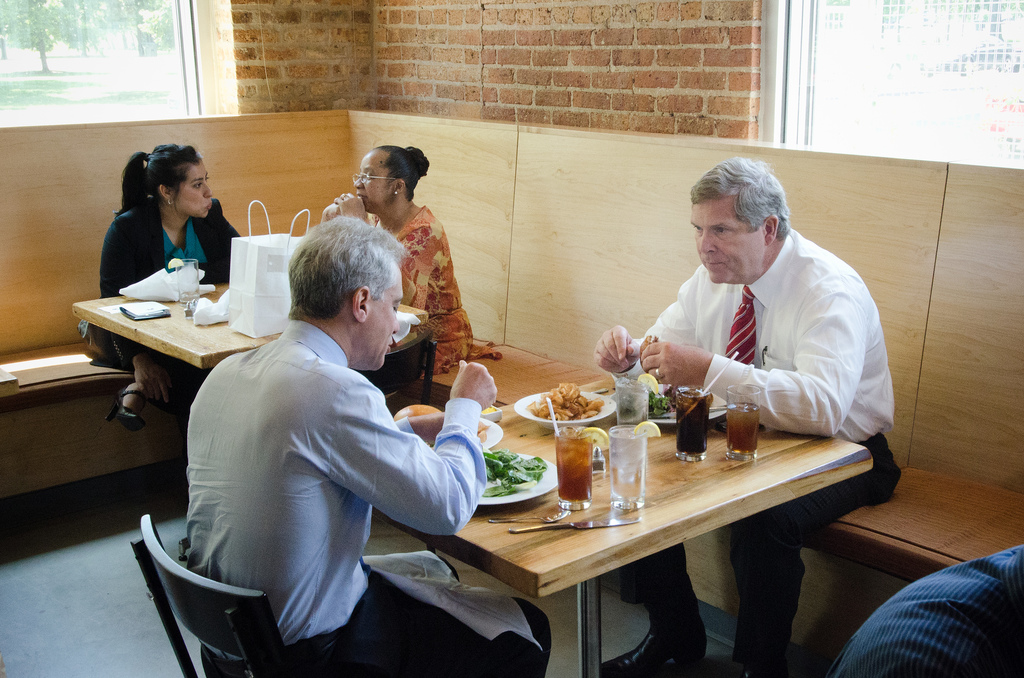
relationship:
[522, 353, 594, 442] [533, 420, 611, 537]
straw in cup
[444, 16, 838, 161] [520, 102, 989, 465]
wall behind bench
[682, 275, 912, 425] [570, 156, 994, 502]
shirt on businessman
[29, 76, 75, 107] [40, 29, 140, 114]
lawn outside window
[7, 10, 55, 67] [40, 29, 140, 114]
tree outside window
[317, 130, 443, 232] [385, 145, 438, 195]
person wears bun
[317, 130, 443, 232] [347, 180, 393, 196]
person wears glasses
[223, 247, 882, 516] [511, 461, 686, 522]
men at table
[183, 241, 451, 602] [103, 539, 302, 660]
man in chair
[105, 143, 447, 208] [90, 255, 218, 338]
women at table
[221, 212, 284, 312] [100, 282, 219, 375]
bag on table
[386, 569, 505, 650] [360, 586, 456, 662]
napkin on lap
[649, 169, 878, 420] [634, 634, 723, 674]
man wearing shoes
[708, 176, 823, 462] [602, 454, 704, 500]
man at table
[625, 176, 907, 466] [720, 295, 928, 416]
man wearing shirt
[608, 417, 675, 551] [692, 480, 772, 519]
glass on table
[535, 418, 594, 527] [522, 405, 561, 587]
glass on table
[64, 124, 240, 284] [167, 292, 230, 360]
woman at table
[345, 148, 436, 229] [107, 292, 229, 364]
woman at table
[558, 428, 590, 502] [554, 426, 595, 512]
tea in cup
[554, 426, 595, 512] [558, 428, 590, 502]
cup on tea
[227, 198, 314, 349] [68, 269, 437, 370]
bag on table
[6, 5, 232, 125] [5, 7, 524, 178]
window on wall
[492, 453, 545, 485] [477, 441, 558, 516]
salad on plate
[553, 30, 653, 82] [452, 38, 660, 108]
brick on wall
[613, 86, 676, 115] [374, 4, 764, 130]
red brick on wall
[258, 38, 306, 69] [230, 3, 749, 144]
brick on wall